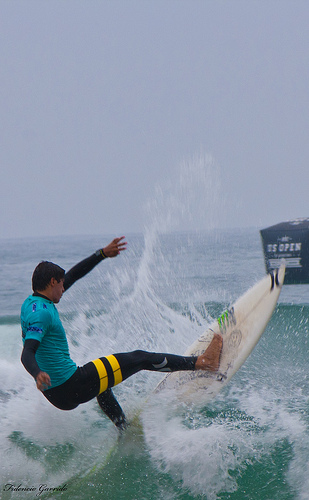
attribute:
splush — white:
[71, 221, 194, 337]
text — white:
[266, 242, 302, 252]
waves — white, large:
[0, 183, 307, 495]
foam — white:
[4, 144, 308, 497]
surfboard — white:
[127, 263, 285, 426]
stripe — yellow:
[91, 352, 123, 394]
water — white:
[87, 153, 226, 343]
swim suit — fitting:
[16, 245, 202, 433]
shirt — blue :
[16, 247, 110, 392]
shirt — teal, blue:
[14, 292, 81, 395]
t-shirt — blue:
[18, 294, 78, 386]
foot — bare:
[198, 332, 224, 375]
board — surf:
[170, 257, 286, 388]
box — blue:
[257, 218, 308, 287]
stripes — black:
[273, 266, 280, 286]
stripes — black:
[268, 270, 274, 289]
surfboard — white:
[120, 260, 284, 463]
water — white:
[77, 250, 220, 321]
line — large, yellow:
[85, 346, 126, 393]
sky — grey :
[2, 0, 305, 238]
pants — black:
[39, 350, 203, 433]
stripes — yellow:
[87, 346, 126, 399]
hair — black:
[28, 260, 68, 293]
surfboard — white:
[106, 267, 285, 455]